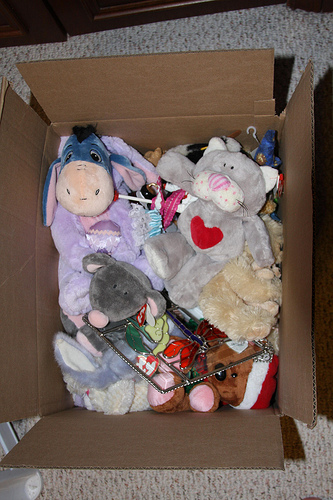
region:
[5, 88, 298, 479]
toys in a cardboard box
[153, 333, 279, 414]
brown teddy bear in a red and white hat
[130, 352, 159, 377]
red and white TY tag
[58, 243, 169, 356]
stuffed gray elephant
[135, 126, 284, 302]
stuffed animal with a red heart on its belly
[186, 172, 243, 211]
pink polka dots on a white background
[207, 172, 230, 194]
pink and white stripes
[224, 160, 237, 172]
two tiny black eyes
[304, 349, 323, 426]
jagged edge of the cardboard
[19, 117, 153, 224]
stuffed Eeyore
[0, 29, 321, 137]
flap of corrugated box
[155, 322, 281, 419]
teddy bear with santa hat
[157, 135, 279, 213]
cat with pink striped nose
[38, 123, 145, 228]
Eeyore in the corner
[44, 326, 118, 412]
a long rabbit ear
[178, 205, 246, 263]
a large red heart on a grey chest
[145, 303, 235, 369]
a dragonfly in a frame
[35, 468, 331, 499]
variegated cream carpet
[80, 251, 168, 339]
mouse with a large pink nose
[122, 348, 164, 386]
a TY lable under frame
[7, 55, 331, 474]
cardboard box of toys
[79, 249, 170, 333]
stuffed elephant toy in box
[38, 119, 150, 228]
stuffed eyeore toy in box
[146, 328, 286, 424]
stuffed bear with santa hat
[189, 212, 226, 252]
heart on belly of teddy bear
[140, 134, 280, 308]
stuffed grey toy with heart on its belly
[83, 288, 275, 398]
stained glass with dragonfly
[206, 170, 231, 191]
pink striped nose on a toy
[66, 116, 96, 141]
black hair on eyore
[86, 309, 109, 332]
pink nose on a stuffed mouse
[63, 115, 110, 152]
black hair of a stuffed animal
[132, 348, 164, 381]
a red and white tag on a bear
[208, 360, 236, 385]
a black nose on a bear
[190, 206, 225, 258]
a red heart on a animal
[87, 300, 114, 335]
pink nose on a mouse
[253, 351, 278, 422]
santa claus hat on a bear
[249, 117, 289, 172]
a blue stuffed animal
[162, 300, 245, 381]
a colorful dragon fly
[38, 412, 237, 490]
a brown card board box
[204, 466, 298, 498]
brown carpet on the floor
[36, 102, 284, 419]
Box full of toys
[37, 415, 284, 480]
Box is open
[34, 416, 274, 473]
The box is made of cardboard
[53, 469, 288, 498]
The box is sitting on carpet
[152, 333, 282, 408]
Teddy bear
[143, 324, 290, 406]
The bear is wearing a santa hat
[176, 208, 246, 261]
Heart on the cat's sweater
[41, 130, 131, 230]
Blue and pink donkey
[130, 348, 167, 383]
TY tag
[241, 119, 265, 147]
Hook to hang the toy